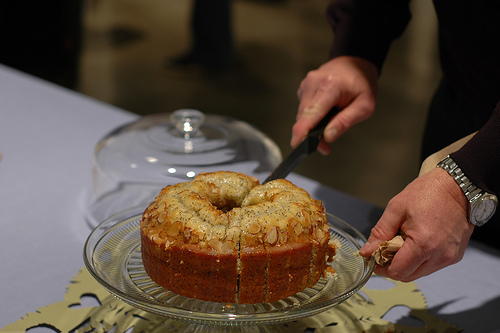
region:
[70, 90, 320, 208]
glass lid on table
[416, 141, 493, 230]
wrist watch on arm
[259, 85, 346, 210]
cutting knife in hand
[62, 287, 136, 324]
heart cutouts in paper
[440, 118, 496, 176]
black sleeves on person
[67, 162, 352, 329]
glass plate under cake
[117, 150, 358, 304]
cake on plate being cut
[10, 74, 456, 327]
white table cloth on table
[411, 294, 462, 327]
shadow of arm on table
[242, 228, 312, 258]
cut pecans on cake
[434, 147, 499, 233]
silver watch with a white face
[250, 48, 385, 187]
person's hand holding a knife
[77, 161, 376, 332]
large glass tray with a cake on top of it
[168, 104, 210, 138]
small glass handle on a tray top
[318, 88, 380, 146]
thumb of a person cutting cake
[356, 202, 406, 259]
thumb of a person cutting cake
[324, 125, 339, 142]
thumbnail of a person cutting cake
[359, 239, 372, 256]
thumbnail of a person cutting cake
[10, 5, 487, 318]
scene of a cake in the process of serving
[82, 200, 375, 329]
white glass raised glass cake display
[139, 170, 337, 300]
lemon poppy seed cake with slivered almonds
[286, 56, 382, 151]
right hand of man serving cake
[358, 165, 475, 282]
left hand of man serving cake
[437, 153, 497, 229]
silver watch on a left wrist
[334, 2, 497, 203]
black long sleeve shirt on a man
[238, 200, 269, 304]
single slice of lemon poppy seed cake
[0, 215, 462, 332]
decorative place mat under cake server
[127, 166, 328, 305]
a sliced cake on a glass holder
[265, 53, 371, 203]
a knife in a right hand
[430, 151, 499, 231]
a silver watch on left arm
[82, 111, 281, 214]
a glass cake lid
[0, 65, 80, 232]
a white table cloth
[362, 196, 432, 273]
a brown napkin in left hand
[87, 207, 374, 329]
a glass cahe holder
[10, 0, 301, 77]
a blurried back ground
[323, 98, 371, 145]
a thumb on a right hand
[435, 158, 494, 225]
Silver watch on person's wrist.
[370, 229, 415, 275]
Person holding napkin in hand.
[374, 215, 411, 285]
Napkin is in person's left hand.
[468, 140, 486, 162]
Person wearing black shirt.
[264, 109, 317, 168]
Person holding knife in hand.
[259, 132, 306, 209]
Person using knife to cut cake.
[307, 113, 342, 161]
Knife has black handle.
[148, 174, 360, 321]
Tan colored cake on cake dish.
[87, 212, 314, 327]
Cake dish is round and clear.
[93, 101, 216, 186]
Clear lid to cake dish.